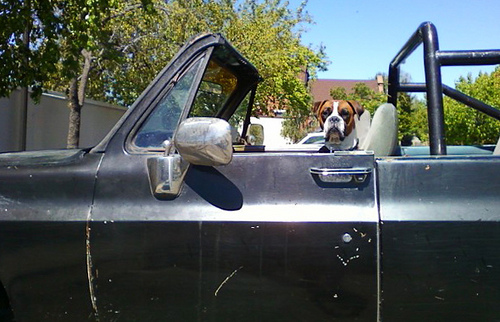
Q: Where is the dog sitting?
A: In a car.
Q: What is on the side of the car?
A: Mirror.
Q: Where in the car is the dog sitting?
A: Front seat.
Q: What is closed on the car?
A: Door.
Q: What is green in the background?
A: Tree.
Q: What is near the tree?
A: White wall.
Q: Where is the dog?
A: In the automobile.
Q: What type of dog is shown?
A: Boxer.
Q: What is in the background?
A: A house.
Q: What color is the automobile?
A: Black.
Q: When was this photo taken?
A: In the afternoon.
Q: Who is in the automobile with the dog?
A: Nobody.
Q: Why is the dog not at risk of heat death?
A: No windows or roof are on the automobile.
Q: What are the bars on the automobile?
A: It's a roll cage.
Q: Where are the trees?
A: On the other side of the automobile.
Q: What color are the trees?
A: Green.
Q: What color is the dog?
A: White and brown.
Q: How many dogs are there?
A: One.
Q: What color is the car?
A: Black.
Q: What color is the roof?
A: Brown.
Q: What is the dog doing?
A: Sitting.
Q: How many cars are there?
A: One.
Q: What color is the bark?
A: Gray.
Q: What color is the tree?
A: Green.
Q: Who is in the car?
A: A dog.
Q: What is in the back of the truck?
A: Metal railing.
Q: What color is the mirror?
A: Silver.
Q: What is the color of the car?
A: Black.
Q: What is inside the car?
A: Dog.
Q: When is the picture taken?
A: Daytime.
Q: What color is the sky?
A: Blue.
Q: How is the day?
A: Sunny.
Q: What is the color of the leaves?
A: Green.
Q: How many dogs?
A: 1.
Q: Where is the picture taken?
A: In front of a car door.